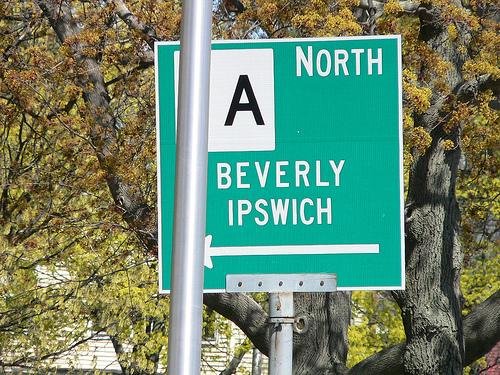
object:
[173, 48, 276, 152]
box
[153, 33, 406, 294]
sign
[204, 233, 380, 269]
arrow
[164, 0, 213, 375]
pole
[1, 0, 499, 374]
tree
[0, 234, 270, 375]
building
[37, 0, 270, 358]
branch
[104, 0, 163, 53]
branch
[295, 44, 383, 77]
north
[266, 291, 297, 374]
pole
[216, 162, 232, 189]
letter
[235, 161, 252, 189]
letter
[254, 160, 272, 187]
letter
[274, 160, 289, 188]
letter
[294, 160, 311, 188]
letter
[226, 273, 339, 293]
bracket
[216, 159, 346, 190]
name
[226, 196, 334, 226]
name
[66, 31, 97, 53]
leaf